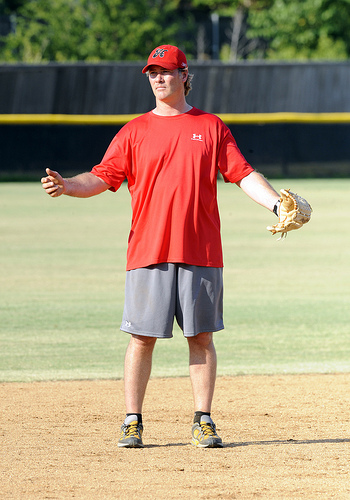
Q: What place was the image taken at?
A: It was taken at the field.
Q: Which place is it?
A: It is a field.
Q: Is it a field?
A: Yes, it is a field.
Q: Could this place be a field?
A: Yes, it is a field.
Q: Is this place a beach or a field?
A: It is a field.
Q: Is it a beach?
A: No, it is a field.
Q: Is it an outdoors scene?
A: Yes, it is outdoors.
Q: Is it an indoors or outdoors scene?
A: It is outdoors.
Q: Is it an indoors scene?
A: No, it is outdoors.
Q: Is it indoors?
A: No, it is outdoors.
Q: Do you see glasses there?
A: No, there are no glasses.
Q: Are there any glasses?
A: No, there are no glasses.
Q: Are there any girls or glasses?
A: No, there are no glasses or girls.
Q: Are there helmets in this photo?
A: No, there are no helmets.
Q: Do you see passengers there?
A: No, there are no passengers.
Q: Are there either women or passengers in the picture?
A: No, there are no passengers or women.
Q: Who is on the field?
A: The man is on the field.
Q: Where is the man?
A: The man is on the field.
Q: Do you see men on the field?
A: Yes, there is a man on the field.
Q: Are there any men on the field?
A: Yes, there is a man on the field.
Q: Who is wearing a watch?
A: The man is wearing a watch.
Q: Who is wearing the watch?
A: The man is wearing a watch.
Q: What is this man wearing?
A: The man is wearing a watch.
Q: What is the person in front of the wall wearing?
A: The man is wearing a watch.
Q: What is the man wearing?
A: The man is wearing a watch.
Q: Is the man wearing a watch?
A: Yes, the man is wearing a watch.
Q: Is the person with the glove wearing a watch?
A: Yes, the man is wearing a watch.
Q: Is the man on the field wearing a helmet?
A: No, the man is wearing a watch.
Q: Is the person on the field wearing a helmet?
A: No, the man is wearing a watch.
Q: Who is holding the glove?
A: The man is holding the glove.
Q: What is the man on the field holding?
A: The man is holding the glove.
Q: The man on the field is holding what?
A: The man is holding the glove.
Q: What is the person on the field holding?
A: The man is holding the glove.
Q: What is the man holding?
A: The man is holding the glove.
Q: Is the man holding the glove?
A: Yes, the man is holding the glove.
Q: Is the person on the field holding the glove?
A: Yes, the man is holding the glove.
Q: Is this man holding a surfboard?
A: No, the man is holding the glove.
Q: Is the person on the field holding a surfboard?
A: No, the man is holding the glove.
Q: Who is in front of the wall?
A: The man is in front of the wall.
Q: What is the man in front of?
A: The man is in front of the wall.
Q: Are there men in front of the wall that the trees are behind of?
A: Yes, there is a man in front of the wall.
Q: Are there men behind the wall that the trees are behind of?
A: No, the man is in front of the wall.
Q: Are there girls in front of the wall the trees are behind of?
A: No, there is a man in front of the wall.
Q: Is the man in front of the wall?
A: Yes, the man is in front of the wall.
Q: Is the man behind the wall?
A: No, the man is in front of the wall.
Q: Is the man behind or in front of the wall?
A: The man is in front of the wall.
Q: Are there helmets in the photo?
A: No, there are no helmets.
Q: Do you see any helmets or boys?
A: No, there are no helmets or boys.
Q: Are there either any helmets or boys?
A: No, there are no helmets or boys.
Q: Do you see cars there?
A: No, there are no cars.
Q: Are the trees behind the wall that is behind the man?
A: Yes, the trees are behind the wall.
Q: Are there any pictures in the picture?
A: No, there are no pictures.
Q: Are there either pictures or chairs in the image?
A: No, there are no pictures or chairs.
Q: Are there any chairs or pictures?
A: No, there are no pictures or chairs.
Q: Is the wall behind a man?
A: Yes, the wall is behind a man.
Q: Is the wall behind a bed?
A: No, the wall is behind a man.